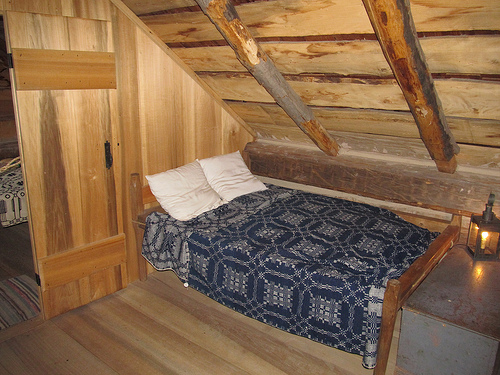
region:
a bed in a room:
[143, 166, 468, 370]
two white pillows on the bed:
[143, 151, 269, 222]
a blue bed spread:
[181, 188, 416, 342]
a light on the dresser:
[466, 194, 498, 257]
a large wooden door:
[7, 12, 144, 294]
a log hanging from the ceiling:
[203, 7, 338, 153]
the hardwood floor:
[36, 320, 254, 367]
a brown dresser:
[407, 234, 499, 373]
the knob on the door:
[103, 148, 113, 167]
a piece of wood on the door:
[11, 47, 118, 89]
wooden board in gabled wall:
[150, 2, 497, 37]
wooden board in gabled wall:
[162, 36, 498, 77]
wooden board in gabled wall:
[197, 69, 497, 104]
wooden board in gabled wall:
[224, 101, 498, 158]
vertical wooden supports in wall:
[352, 8, 477, 173]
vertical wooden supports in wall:
[194, 8, 341, 159]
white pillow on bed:
[134, 156, 219, 231]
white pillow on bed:
[200, 149, 266, 207]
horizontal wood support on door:
[11, 42, 123, 102]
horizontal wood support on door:
[34, 231, 142, 285]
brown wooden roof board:
[281, 74, 405, 112]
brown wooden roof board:
[305, 106, 422, 143]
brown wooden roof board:
[260, 37, 392, 79]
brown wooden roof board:
[230, 4, 374, 36]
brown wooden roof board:
[447, 119, 497, 144]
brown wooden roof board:
[434, 79, 498, 119]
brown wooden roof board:
[416, 35, 496, 76]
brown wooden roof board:
[407, 2, 497, 33]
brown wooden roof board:
[227, 103, 298, 131]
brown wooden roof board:
[171, 39, 249, 74]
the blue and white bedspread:
[142, 187, 430, 357]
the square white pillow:
[145, 162, 217, 224]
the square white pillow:
[202, 155, 261, 197]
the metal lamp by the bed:
[466, 200, 497, 257]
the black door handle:
[102, 138, 114, 168]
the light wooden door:
[6, 10, 137, 307]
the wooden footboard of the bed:
[370, 208, 472, 359]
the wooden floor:
[0, 267, 373, 374]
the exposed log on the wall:
[202, 0, 342, 153]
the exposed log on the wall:
[365, 2, 459, 174]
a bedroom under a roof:
[6, 9, 493, 370]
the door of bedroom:
[1, 11, 139, 314]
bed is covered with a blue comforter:
[134, 146, 458, 363]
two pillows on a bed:
[131, 142, 271, 223]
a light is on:
[459, 180, 499, 282]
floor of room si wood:
[27, 308, 283, 368]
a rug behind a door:
[3, 261, 50, 335]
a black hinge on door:
[3, 47, 18, 75]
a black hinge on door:
[29, 266, 44, 292]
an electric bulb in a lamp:
[478, 223, 491, 250]